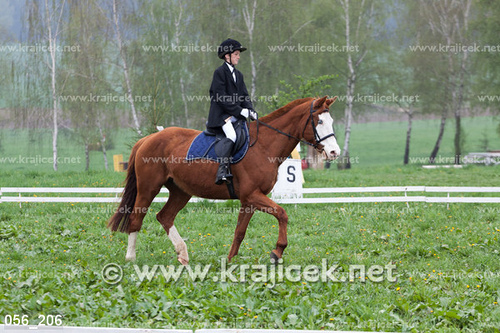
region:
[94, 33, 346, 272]
person riding a horse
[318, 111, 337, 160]
white face on brown horse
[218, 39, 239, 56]
black helmet rider is wearing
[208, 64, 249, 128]
black coat rider is wearing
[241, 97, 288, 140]
black reins the rider is holding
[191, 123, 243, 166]
blue blanket under the saddle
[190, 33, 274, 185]
woman is wearing a black and white outfit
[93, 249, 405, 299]
Website address is advertised on the watermark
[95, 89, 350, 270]
Horse is trotting through the grass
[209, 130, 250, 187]
Rider is wearing long black boots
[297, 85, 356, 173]
Horse has white fur on its nose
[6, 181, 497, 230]
White and short fence runs along the background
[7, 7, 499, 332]
watermark appears all over the picture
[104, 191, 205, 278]
Horse has white fur on its rear legs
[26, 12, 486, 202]
Tall birch trees are seen behind the horse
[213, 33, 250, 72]
Rider wearing a large black helmet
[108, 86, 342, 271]
a brown horse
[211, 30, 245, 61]
a black hat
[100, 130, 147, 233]
a hairy tail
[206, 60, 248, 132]
a black coat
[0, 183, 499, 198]
the track for horses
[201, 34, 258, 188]
a lady on the horse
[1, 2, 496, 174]
trees in the field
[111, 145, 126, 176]
an orange object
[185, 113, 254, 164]
a blue saddle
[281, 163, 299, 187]
the number five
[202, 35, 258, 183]
a woman riding a horse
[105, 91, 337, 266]
a brown and white horse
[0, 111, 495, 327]
a large green pasture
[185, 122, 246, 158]
blue cloth under the saddle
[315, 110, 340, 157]
white snout of the horse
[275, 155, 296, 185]
sign with a black 's'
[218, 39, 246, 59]
a black riding helmet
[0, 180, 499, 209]
small white fence in the pasture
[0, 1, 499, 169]
a row of trees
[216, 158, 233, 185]
black boot on the woman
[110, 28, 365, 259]
woman riding a horse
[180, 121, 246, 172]
blue blanket on horse back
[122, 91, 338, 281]
brown horse with white on face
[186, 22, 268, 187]
woman wearing black hat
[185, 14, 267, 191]
woman wearing black boots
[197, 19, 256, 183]
woman wearing black coat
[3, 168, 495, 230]
small white picket fence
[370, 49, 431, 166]
skinny tree with leaves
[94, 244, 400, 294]
website on picture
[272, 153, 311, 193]
white sign with black letter S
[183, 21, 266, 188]
woman sitting on a horse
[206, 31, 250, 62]
woman wearing a black hat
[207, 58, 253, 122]
woman wearing a black jacket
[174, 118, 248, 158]
blue blanket under the saddle